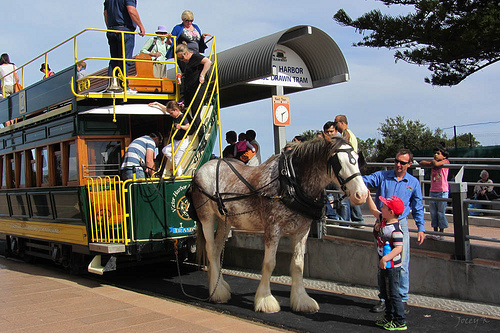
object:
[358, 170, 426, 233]
shirt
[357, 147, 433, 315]
man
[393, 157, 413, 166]
sunglasses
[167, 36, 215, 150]
people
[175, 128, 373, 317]
horse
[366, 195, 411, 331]
kid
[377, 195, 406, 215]
cap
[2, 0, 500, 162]
sky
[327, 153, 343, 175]
cover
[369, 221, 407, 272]
shirt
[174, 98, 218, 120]
stairs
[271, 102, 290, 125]
clock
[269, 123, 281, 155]
pole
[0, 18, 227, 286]
carriage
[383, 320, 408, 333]
sneakers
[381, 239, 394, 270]
bottle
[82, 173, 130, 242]
gate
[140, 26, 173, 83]
person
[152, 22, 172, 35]
hat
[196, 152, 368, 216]
halter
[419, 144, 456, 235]
child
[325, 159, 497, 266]
fence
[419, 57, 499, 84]
branches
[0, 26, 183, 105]
rail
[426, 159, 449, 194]
shirt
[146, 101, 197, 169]
girl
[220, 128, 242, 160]
people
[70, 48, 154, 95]
bench